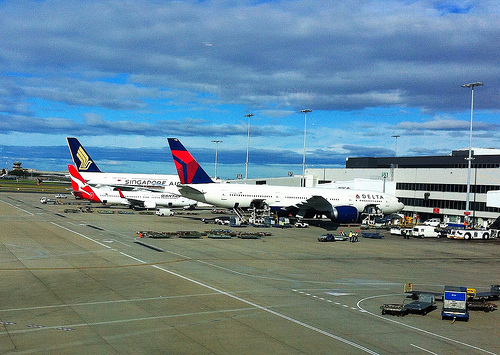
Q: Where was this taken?
A: An airport.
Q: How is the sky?
A: Cloudy and blue.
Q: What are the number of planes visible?
A: At least three.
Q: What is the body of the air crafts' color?
A: White.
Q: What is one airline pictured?
A: Singapore Airlines.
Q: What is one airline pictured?
A: Delta.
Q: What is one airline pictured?
A: Qantas Airlines.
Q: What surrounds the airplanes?
A: Smaller vehicles.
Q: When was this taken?
A: Maybe late afternoon.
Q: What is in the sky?
A: Clouds.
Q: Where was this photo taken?
A: An airport.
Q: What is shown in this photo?
A: A parking lot.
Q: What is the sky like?
A: Clear and blue.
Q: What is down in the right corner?
A: Cars parked.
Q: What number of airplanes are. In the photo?
A: Two.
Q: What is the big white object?
A: Planes.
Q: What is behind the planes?
A: Building.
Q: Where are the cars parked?
A: In parking lot.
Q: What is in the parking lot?
A: White lines.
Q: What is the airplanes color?
A: White.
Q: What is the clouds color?
A: White.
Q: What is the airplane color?
A: Red,white and blue.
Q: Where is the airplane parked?
A: In runway.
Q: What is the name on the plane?
A: Delta.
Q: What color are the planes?
A: White.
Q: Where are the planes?
A: Parked at the jetway.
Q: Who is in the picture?
A: No one.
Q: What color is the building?
A: Black and white.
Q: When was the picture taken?
A: In the daytime.